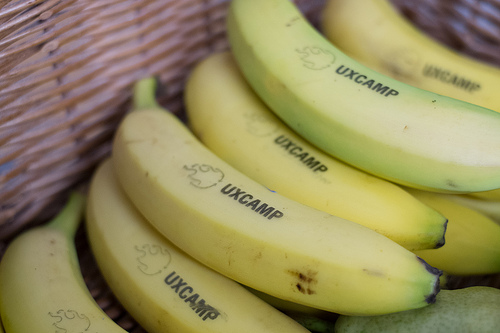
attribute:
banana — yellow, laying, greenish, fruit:
[144, 136, 375, 272]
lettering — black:
[222, 176, 285, 230]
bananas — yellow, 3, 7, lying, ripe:
[112, 44, 435, 294]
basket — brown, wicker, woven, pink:
[1, 22, 165, 100]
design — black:
[294, 38, 342, 74]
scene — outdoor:
[23, 9, 498, 303]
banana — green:
[276, 28, 490, 142]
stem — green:
[128, 74, 163, 109]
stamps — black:
[266, 130, 332, 174]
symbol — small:
[304, 41, 330, 68]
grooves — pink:
[53, 28, 157, 43]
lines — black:
[38, 31, 169, 63]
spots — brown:
[294, 265, 324, 297]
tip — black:
[435, 270, 449, 302]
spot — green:
[406, 84, 453, 109]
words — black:
[276, 133, 333, 178]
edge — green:
[302, 26, 494, 127]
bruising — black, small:
[278, 254, 335, 301]